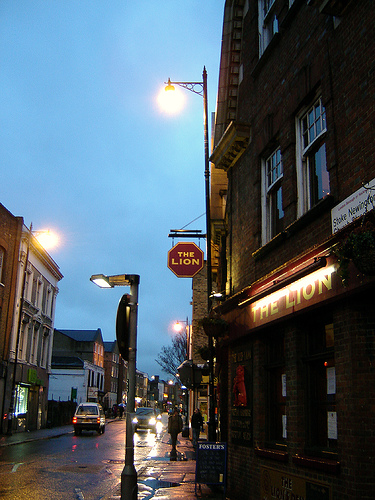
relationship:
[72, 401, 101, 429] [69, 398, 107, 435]
back of car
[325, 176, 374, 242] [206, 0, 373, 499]
sign on apartment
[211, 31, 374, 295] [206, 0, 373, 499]
story of apartment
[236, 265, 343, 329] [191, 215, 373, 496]
sign to restaurant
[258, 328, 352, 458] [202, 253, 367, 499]
windows of a restaurant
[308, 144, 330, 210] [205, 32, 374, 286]
window of an apartment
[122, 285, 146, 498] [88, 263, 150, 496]
pole to light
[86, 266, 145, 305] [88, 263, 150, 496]
light to light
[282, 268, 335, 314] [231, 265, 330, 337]
word lion on sign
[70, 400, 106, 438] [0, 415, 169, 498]
car on road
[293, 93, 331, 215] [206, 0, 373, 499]
window on apartment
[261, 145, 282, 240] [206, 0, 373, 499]
window on apartment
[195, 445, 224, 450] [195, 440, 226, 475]
writing on sign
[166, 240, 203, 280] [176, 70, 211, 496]
sign on pole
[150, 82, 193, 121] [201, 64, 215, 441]
street light on lamp post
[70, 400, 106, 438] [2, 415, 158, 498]
car on street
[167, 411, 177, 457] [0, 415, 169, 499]
person walking on road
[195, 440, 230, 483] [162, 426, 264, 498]
sign on sidewalk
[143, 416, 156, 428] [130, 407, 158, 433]
headlight on car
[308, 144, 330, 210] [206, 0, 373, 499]
window on apartment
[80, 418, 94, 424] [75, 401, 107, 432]
licence on vehicle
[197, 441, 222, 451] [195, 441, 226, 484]
lettering on sign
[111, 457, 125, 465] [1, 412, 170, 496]
manhole lid in street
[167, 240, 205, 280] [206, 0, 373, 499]
sign next to apartment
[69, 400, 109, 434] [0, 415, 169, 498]
car on road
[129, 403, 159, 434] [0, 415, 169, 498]
car on road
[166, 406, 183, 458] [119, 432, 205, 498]
person on sidewalk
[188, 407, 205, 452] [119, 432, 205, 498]
person on sidewalk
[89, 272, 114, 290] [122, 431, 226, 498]
light on sidewalk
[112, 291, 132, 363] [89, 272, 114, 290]
sign on light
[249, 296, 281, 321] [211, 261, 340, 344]
word on sign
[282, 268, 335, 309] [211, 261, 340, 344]
word lion on sign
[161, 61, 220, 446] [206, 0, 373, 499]
lamp post next to apartment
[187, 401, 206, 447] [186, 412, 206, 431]
person wears sweater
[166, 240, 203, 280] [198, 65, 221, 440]
sign on post